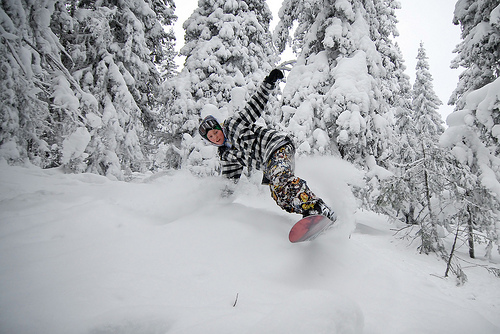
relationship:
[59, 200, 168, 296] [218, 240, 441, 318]
snow on ground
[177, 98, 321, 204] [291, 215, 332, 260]
woman on board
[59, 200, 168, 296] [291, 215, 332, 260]
snow on board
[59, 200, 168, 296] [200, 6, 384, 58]
snow on trees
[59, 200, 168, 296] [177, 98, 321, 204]
snow on woman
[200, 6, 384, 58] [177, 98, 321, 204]
trees behind woman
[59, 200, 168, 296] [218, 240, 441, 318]
snow in ground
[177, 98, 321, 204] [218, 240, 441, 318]
woman off ground